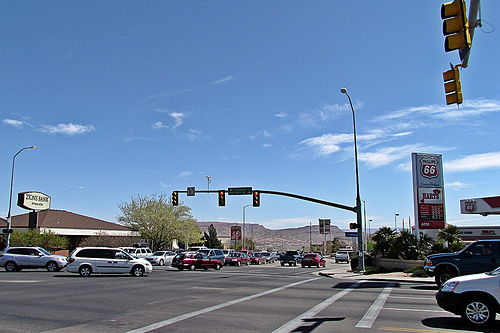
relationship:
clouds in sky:
[150, 102, 394, 169] [14, 4, 255, 50]